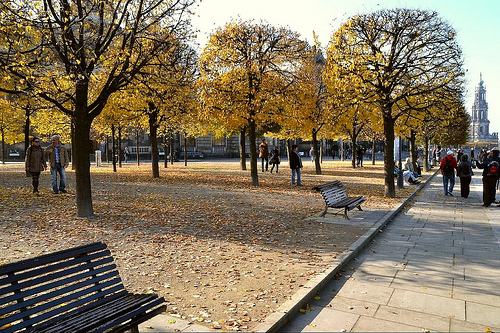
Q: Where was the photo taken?
A: It was taken at the park.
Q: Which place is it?
A: It is a park.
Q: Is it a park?
A: Yes, it is a park.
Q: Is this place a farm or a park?
A: It is a park.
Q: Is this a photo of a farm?
A: No, the picture is showing a park.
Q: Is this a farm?
A: No, it is a park.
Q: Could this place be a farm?
A: No, it is a park.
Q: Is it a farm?
A: No, it is a park.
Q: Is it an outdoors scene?
A: Yes, it is outdoors.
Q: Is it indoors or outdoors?
A: It is outdoors.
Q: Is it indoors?
A: No, it is outdoors.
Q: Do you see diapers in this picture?
A: No, there are no diapers.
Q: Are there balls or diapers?
A: No, there are no diapers or balls.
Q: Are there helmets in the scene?
A: No, there are no helmets.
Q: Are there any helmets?
A: No, there are no helmets.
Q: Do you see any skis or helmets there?
A: No, there are no helmets or skis.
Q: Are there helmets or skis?
A: No, there are no helmets or skis.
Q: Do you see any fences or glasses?
A: No, there are no fences or glasses.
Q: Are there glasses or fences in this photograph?
A: No, there are no fences or glasses.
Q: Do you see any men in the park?
A: Yes, there is a man in the park.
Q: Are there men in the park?
A: Yes, there is a man in the park.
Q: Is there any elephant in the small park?
A: No, there is a man in the park.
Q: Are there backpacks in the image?
A: Yes, there is a backpack.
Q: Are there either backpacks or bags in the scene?
A: Yes, there is a backpack.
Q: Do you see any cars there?
A: No, there are no cars.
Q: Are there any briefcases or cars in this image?
A: No, there are no cars or briefcases.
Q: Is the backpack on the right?
A: Yes, the backpack is on the right of the image.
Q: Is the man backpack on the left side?
A: No, the backpack is on the right of the image.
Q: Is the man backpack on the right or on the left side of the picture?
A: The backpack is on the right of the image.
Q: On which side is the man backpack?
A: The backpack is on the right of the image.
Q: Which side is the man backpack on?
A: The backpack is on the right of the image.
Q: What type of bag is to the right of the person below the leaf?
A: The bag is a backpack.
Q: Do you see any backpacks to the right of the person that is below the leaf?
A: Yes, there is a backpack to the right of the person.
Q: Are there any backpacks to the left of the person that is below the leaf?
A: No, the backpack is to the right of the person.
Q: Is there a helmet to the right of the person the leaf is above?
A: No, there is a backpack to the right of the person.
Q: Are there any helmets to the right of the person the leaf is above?
A: No, there is a backpack to the right of the person.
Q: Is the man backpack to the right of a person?
A: Yes, the backpack is to the right of a person.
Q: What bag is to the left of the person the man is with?
A: The bag is a backpack.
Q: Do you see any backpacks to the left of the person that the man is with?
A: Yes, there is a backpack to the left of the person.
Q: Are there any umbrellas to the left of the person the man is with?
A: No, there is a backpack to the left of the person.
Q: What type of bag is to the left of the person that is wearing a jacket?
A: The bag is a backpack.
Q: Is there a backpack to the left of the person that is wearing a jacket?
A: Yes, there is a backpack to the left of the person.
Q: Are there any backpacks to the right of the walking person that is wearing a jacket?
A: No, the backpack is to the left of the person.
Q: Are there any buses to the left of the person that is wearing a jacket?
A: No, there is a backpack to the left of the person.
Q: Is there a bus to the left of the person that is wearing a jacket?
A: No, there is a backpack to the left of the person.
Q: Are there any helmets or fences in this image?
A: No, there are no fences or helmets.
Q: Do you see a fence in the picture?
A: No, there are no fences.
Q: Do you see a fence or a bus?
A: No, there are no fences or buses.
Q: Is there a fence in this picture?
A: No, there are no fences.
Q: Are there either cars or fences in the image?
A: No, there are no fences or cars.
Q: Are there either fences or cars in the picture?
A: No, there are no fences or cars.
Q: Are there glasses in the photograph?
A: No, there are no glasses.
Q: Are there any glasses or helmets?
A: No, there are no glasses or helmets.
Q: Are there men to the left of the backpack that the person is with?
A: Yes, there is a man to the left of the backpack.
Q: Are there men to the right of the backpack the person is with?
A: No, the man is to the left of the backpack.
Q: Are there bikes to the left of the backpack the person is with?
A: No, there is a man to the left of the backpack.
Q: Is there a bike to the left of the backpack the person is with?
A: No, there is a man to the left of the backpack.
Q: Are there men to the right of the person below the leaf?
A: Yes, there is a man to the right of the person.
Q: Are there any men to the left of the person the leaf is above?
A: No, the man is to the right of the person.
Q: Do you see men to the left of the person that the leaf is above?
A: No, the man is to the right of the person.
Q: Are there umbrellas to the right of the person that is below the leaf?
A: No, there is a man to the right of the person.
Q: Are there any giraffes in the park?
A: No, there is a man in the park.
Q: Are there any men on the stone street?
A: Yes, there is a man on the street.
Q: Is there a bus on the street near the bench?
A: No, there is a man on the street.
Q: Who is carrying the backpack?
A: The man is carrying the backpack.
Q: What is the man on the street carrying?
A: The man is carrying a backpack.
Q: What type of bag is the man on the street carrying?
A: The man is carrying a backpack.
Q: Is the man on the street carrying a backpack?
A: Yes, the man is carrying a backpack.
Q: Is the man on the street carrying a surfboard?
A: No, the man is carrying a backpack.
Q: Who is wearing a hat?
A: The man is wearing a hat.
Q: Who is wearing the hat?
A: The man is wearing a hat.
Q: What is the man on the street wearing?
A: The man is wearing a hat.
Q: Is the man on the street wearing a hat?
A: Yes, the man is wearing a hat.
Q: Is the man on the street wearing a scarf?
A: No, the man is wearing a hat.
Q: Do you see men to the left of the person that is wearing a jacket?
A: Yes, there is a man to the left of the person.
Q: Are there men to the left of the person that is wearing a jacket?
A: Yes, there is a man to the left of the person.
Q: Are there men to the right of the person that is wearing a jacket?
A: No, the man is to the left of the person.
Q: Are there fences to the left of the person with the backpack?
A: No, there is a man to the left of the person.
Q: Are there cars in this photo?
A: No, there are no cars.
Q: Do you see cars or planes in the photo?
A: No, there are no cars or planes.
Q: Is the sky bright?
A: Yes, the sky is bright.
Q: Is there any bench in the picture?
A: Yes, there is a bench.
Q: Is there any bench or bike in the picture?
A: Yes, there is a bench.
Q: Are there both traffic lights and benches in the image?
A: No, there is a bench but no traffic lights.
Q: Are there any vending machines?
A: No, there are no vending machines.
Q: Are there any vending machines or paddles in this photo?
A: No, there are no vending machines or paddles.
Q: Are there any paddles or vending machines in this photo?
A: No, there are no vending machines or paddles.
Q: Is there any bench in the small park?
A: Yes, there is a bench in the park.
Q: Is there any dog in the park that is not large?
A: No, there is a bench in the park.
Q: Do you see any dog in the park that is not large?
A: No, there is a bench in the park.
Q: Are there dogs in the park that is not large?
A: No, there is a bench in the park.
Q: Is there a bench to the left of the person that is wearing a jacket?
A: Yes, there is a bench to the left of the person.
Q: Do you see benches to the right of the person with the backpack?
A: No, the bench is to the left of the person.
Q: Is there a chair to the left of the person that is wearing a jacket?
A: No, there is a bench to the left of the person.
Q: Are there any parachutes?
A: No, there are no parachutes.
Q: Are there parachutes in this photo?
A: No, there are no parachutes.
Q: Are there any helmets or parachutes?
A: No, there are no parachutes or helmets.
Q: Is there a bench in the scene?
A: Yes, there is a bench.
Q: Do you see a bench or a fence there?
A: Yes, there is a bench.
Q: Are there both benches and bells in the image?
A: No, there is a bench but no bells.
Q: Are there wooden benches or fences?
A: Yes, there is a wood bench.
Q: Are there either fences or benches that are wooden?
A: Yes, the bench is wooden.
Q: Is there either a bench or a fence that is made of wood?
A: Yes, the bench is made of wood.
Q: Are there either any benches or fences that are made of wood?
A: Yes, the bench is made of wood.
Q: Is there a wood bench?
A: Yes, there is a bench that is made of wood.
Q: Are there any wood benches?
A: Yes, there is a bench that is made of wood.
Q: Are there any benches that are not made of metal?
A: Yes, there is a bench that is made of wood.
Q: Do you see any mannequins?
A: No, there are no mannequins.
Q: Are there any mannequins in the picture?
A: No, there are no mannequins.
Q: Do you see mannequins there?
A: No, there are no mannequins.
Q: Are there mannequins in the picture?
A: No, there are no mannequins.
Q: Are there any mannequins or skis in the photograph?
A: No, there are no mannequins or skis.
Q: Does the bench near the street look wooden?
A: Yes, the bench is wooden.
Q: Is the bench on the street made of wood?
A: Yes, the bench is made of wood.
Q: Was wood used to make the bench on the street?
A: Yes, the bench is made of wood.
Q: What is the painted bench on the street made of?
A: The bench is made of wood.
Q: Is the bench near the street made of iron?
A: No, the bench is made of wood.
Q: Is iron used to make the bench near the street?
A: No, the bench is made of wood.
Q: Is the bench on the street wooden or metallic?
A: The bench is wooden.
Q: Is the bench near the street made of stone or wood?
A: The bench is made of wood.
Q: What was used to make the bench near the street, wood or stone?
A: The bench is made of wood.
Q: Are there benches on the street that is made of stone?
A: Yes, there is a bench on the street.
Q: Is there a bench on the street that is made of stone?
A: Yes, there is a bench on the street.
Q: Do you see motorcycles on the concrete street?
A: No, there is a bench on the street.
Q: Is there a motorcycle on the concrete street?
A: No, there is a bench on the street.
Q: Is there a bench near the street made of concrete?
A: Yes, there is a bench near the street.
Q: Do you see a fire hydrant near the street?
A: No, there is a bench near the street.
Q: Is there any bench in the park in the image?
A: Yes, there is a bench in the park.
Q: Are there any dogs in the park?
A: No, there is a bench in the park.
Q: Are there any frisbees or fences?
A: No, there are no fences or frisbees.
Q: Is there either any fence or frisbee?
A: No, there are no fences or frisbees.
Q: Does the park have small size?
A: Yes, the park is small.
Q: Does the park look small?
A: Yes, the park is small.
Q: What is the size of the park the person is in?
A: The park is small.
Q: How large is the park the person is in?
A: The park is small.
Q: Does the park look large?
A: No, the park is small.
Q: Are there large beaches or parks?
A: No, there is a park but it is small.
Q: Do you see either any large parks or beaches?
A: No, there is a park but it is small.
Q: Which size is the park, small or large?
A: The park is small.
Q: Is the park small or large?
A: The park is small.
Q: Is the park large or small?
A: The park is small.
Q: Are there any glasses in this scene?
A: No, there are no glasses.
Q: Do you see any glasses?
A: No, there are no glasses.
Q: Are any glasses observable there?
A: No, there are no glasses.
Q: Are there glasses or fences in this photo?
A: No, there are no glasses or fences.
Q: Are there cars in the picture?
A: No, there are no cars.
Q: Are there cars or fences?
A: No, there are no cars or fences.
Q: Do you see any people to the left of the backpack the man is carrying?
A: Yes, there is a person to the left of the backpack.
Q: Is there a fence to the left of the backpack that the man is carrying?
A: No, there is a person to the left of the backpack.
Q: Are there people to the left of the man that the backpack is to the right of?
A: Yes, there is a person to the left of the man.